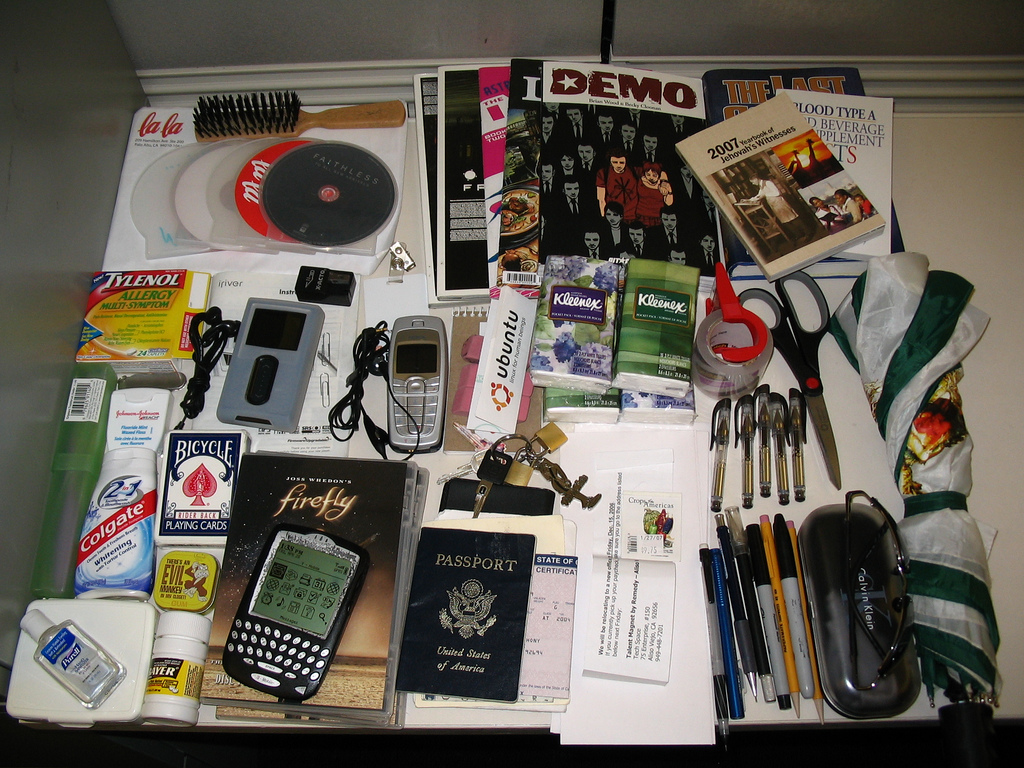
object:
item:
[710, 397, 734, 510]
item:
[692, 263, 775, 401]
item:
[736, 271, 845, 493]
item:
[673, 90, 886, 281]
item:
[611, 259, 699, 398]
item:
[736, 393, 758, 509]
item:
[755, 376, 775, 495]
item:
[772, 392, 792, 505]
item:
[786, 389, 808, 502]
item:
[436, 421, 601, 520]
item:
[389, 315, 447, 453]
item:
[698, 544, 730, 751]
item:
[707, 512, 762, 706]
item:
[710, 549, 745, 718]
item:
[723, 509, 758, 700]